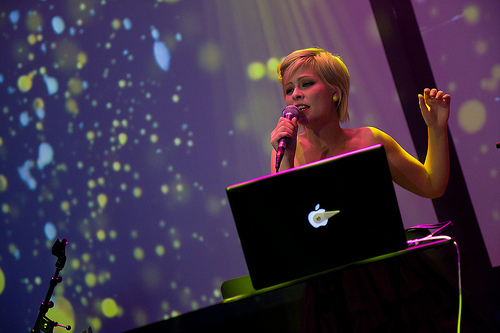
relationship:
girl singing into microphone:
[254, 43, 463, 220] [267, 103, 302, 165]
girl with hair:
[266, 46, 454, 200] [315, 50, 347, 94]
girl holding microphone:
[266, 46, 454, 200] [275, 104, 299, 169]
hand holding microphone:
[269, 117, 296, 152] [272, 102, 300, 122]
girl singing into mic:
[266, 46, 454, 200] [273, 103, 299, 172]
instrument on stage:
[33, 237, 76, 331] [0, 0, 496, 332]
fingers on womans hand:
[417, 85, 452, 107] [413, 81, 456, 134]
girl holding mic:
[266, 46, 454, 200] [277, 100, 299, 166]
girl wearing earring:
[266, 46, 454, 200] [324, 88, 342, 106]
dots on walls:
[34, 21, 181, 179] [13, 15, 221, 272]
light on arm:
[362, 122, 434, 176] [360, 128, 449, 193]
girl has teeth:
[266, 46, 454, 200] [294, 102, 307, 107]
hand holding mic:
[266, 117, 296, 152] [273, 103, 299, 172]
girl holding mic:
[266, 46, 454, 200] [273, 103, 299, 172]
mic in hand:
[273, 103, 299, 172] [269, 114, 299, 160]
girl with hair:
[266, 46, 454, 200] [280, 46, 349, 121]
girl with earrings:
[266, 46, 454, 200] [332, 94, 339, 102]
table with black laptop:
[127, 237, 469, 331] [226, 141, 405, 292]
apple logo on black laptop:
[297, 190, 333, 232] [212, 139, 403, 279]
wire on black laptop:
[408, 235, 464, 331] [226, 141, 405, 292]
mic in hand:
[273, 103, 299, 172] [270, 118, 297, 145]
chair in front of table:
[214, 269, 256, 299] [93, 231, 466, 331]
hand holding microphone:
[372, 70, 459, 230] [269, 105, 298, 170]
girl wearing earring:
[266, 46, 454, 200] [324, 81, 347, 113]